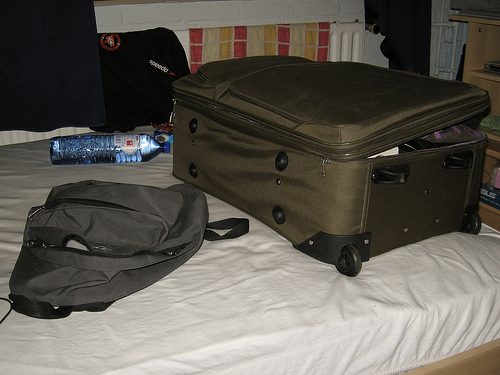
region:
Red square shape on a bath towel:
[186, 26, 207, 45]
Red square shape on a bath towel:
[185, 41, 206, 61]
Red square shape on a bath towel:
[229, 22, 247, 42]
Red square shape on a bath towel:
[232, 36, 247, 60]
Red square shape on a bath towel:
[273, 21, 293, 40]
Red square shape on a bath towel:
[273, 37, 294, 54]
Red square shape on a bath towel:
[315, 18, 329, 26]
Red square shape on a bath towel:
[313, 27, 333, 50]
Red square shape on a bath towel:
[313, 46, 340, 61]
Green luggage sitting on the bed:
[162, 43, 499, 329]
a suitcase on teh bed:
[122, 31, 468, 348]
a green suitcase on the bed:
[137, 45, 383, 332]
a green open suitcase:
[179, 58, 441, 356]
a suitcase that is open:
[187, 37, 449, 339]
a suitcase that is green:
[149, 39, 456, 350]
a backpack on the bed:
[42, 138, 199, 368]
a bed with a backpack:
[22, 134, 274, 314]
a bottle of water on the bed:
[1, 101, 265, 252]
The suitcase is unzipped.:
[348, 96, 492, 175]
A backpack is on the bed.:
[9, 180, 207, 320]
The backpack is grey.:
[104, 198, 169, 243]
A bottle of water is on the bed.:
[49, 131, 169, 167]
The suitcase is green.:
[290, 171, 357, 223]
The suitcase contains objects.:
[418, 123, 477, 147]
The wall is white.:
[197, 0, 289, 21]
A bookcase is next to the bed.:
[452, 15, 498, 77]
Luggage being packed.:
[170, 53, 491, 274]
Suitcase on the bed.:
[162, 50, 493, 277]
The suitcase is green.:
[165, 50, 492, 271]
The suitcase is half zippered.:
[165, 48, 490, 269]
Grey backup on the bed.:
[5, 178, 250, 324]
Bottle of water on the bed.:
[48, 128, 170, 166]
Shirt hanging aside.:
[95, 25, 182, 135]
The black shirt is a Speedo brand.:
[96, 26, 181, 133]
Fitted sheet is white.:
[2, 134, 497, 374]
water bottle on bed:
[44, 120, 171, 166]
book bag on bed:
[5, 157, 221, 345]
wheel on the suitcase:
[330, 247, 358, 279]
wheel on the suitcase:
[372, 167, 411, 186]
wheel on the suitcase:
[445, 202, 482, 241]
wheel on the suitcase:
[442, 153, 477, 176]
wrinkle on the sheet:
[315, 306, 357, 326]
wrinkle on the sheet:
[423, 315, 463, 343]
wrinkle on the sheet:
[435, 259, 472, 286]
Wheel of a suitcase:
[338, 242, 365, 279]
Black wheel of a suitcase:
[338, 243, 366, 281]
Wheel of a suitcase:
[464, 207, 485, 239]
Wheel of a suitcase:
[468, 208, 485, 238]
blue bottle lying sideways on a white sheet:
[48, 129, 170, 164]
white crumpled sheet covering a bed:
[0, 126, 498, 370]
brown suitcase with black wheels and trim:
[169, 51, 499, 278]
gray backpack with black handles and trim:
[3, 178, 251, 327]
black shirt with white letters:
[94, 25, 191, 135]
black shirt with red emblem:
[95, 24, 189, 130]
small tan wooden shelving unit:
[446, 6, 498, 235]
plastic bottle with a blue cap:
[48, 130, 170, 164]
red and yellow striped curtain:
[171, 21, 330, 71]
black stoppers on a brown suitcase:
[181, 112, 292, 229]